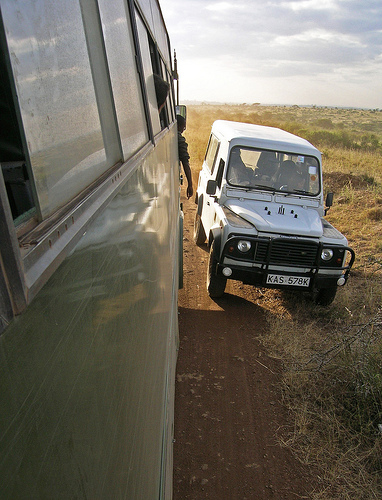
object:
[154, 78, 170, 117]
men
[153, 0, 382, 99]
white cloud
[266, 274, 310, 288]
black white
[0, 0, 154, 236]
windows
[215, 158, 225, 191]
windows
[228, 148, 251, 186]
man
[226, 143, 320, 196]
windshield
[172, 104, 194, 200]
man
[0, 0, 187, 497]
bus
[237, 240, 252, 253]
light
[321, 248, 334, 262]
light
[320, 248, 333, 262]
headlights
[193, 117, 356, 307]
jeep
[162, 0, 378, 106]
blue sky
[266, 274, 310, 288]
license plate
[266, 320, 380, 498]
grass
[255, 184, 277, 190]
windshield wipers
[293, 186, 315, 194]
windshield wipers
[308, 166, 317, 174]
stickers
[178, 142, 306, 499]
dirt road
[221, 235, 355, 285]
cow catcher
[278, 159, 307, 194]
man